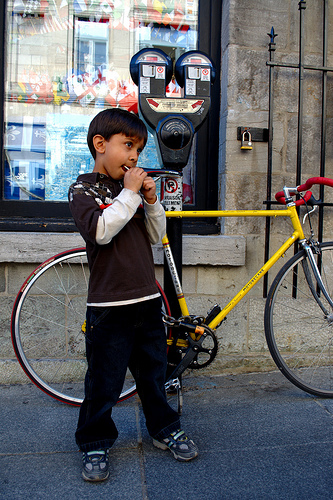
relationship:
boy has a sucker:
[70, 109, 199, 482] [120, 162, 128, 172]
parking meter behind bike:
[129, 46, 215, 168] [8, 175, 331, 406]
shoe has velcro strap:
[151, 428, 200, 461] [166, 430, 187, 444]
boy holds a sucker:
[70, 109, 199, 482] [120, 162, 128, 172]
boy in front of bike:
[70, 109, 199, 482] [8, 175, 331, 406]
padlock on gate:
[240, 130, 252, 152] [239, 0, 330, 300]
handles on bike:
[270, 176, 332, 209] [8, 175, 331, 406]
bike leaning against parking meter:
[8, 175, 331, 406] [129, 46, 215, 168]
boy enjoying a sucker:
[70, 109, 199, 482] [120, 162, 128, 172]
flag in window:
[73, 66, 109, 110] [4, 0, 199, 204]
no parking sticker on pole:
[157, 175, 182, 209] [160, 169, 183, 311]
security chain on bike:
[160, 310, 201, 326] [8, 175, 331, 406]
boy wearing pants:
[70, 109, 199, 482] [73, 295, 181, 454]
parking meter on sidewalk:
[129, 46, 215, 168] [1, 365, 331, 498]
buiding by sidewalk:
[1, 0, 331, 384] [1, 365, 331, 498]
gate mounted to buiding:
[239, 0, 330, 300] [1, 0, 331, 384]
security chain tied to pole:
[160, 310, 201, 326] [160, 169, 183, 311]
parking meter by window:
[129, 46, 215, 168] [4, 0, 199, 204]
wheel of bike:
[10, 246, 171, 407] [8, 175, 331, 406]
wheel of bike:
[261, 243, 331, 400] [8, 175, 331, 406]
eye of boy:
[120, 141, 133, 152] [70, 109, 199, 482]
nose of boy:
[127, 149, 139, 163] [70, 109, 199, 482]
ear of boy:
[91, 133, 105, 156] [70, 109, 199, 482]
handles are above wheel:
[270, 176, 332, 209] [261, 243, 331, 400]